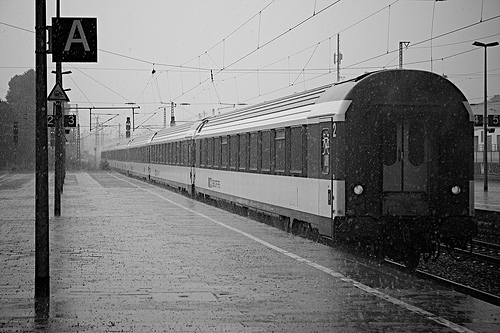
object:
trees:
[4, 67, 39, 166]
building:
[471, 112, 500, 187]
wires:
[102, 0, 343, 135]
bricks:
[65, 249, 94, 257]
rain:
[0, 0, 500, 331]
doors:
[379, 105, 436, 220]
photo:
[0, 0, 500, 333]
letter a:
[53, 20, 99, 60]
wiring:
[97, 14, 500, 148]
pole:
[52, 83, 68, 218]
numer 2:
[45, 115, 54, 126]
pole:
[57, 99, 64, 220]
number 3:
[66, 116, 79, 127]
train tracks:
[377, 238, 499, 301]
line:
[104, 169, 476, 333]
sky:
[0, 3, 499, 157]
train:
[98, 69, 478, 271]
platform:
[0, 170, 499, 332]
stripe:
[100, 161, 348, 218]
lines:
[62, 66, 97, 110]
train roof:
[99, 66, 477, 154]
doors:
[376, 110, 432, 201]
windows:
[405, 123, 427, 166]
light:
[350, 181, 376, 199]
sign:
[49, 16, 98, 63]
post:
[24, 1, 53, 333]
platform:
[470, 173, 498, 214]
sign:
[45, 114, 56, 127]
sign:
[62, 115, 78, 128]